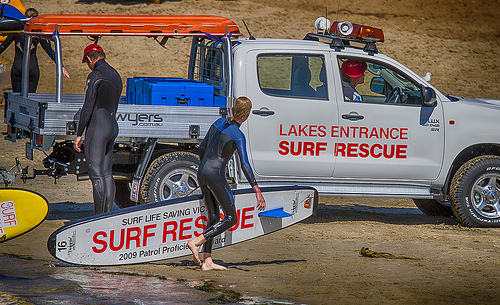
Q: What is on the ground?
A: Dirt.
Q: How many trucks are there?
A: One.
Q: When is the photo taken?
A: Day time.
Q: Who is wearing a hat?
A: The man.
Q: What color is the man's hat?
A: Red.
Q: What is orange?
A: The raft.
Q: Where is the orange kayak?
A: The truck.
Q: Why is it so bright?
A: Sunny.